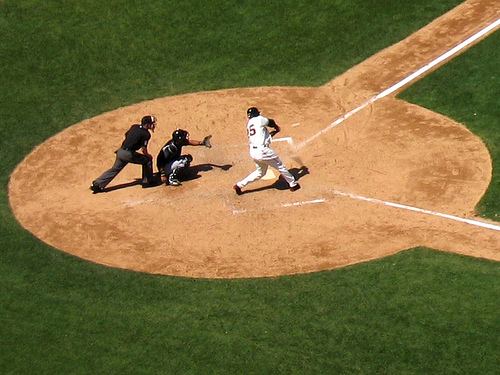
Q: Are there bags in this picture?
A: No, there are no bags.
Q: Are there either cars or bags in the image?
A: No, there are no bags or cars.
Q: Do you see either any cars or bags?
A: No, there are no bags or cars.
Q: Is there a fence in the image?
A: No, there are no fences.